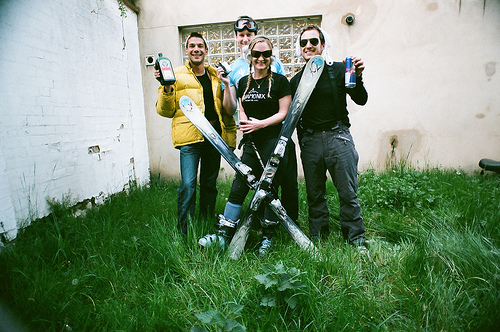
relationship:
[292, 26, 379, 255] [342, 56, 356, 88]
person holding red bull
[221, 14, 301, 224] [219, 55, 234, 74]
person holding bottle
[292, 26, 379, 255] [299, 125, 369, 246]
person wearing pants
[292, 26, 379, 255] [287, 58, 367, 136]
person wearing shirt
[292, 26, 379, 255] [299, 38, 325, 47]
person has sunglasses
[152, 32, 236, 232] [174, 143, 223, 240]
man wearing jeans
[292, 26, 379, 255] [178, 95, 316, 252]
person posing with skis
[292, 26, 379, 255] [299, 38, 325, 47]
person wearing sunglasses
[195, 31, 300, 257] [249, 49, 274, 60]
person wearing sunglasses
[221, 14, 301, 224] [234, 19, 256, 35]
person wearing goggles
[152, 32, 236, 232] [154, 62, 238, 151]
man has jacket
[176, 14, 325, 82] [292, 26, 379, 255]
window behind person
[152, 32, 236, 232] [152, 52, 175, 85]
man holding bottle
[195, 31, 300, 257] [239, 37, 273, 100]
person has hair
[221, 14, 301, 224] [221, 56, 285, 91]
person wearing shirt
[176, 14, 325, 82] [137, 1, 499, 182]
window in wall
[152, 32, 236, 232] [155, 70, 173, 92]
man has hand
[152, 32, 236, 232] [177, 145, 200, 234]
man has leg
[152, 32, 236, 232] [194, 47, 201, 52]
man has nose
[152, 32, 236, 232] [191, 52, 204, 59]
man has mouth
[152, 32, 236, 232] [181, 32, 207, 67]
man has head